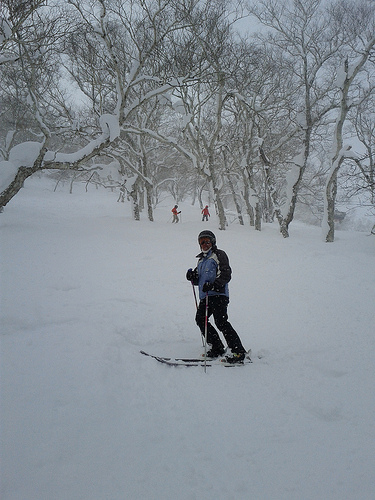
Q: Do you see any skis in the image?
A: Yes, there are skis.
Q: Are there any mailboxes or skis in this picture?
A: Yes, there are skis.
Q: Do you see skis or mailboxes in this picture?
A: Yes, there are skis.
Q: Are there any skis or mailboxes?
A: Yes, there are skis.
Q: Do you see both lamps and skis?
A: No, there are skis but no lamps.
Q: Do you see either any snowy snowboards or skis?
A: Yes, there are snowy skis.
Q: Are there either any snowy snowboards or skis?
A: Yes, there are snowy skis.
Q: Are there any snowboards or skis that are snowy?
A: Yes, the skis are snowy.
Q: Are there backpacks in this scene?
A: No, there are no backpacks.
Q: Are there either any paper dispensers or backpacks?
A: No, there are no backpacks or paper dispensers.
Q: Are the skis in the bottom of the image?
A: Yes, the skis are in the bottom of the image.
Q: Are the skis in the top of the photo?
A: No, the skis are in the bottom of the image.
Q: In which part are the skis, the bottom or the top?
A: The skis are in the bottom of the image.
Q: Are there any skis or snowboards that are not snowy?
A: No, there are skis but they are snowy.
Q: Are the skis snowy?
A: Yes, the skis are snowy.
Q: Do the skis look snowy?
A: Yes, the skis are snowy.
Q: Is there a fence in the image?
A: No, there are no fences.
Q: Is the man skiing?
A: Yes, the man is skiing.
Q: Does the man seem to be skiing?
A: Yes, the man is skiing.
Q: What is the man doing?
A: The man is skiing.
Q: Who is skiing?
A: The man is skiing.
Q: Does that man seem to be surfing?
A: No, the man is skiing.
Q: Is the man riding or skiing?
A: The man is skiing.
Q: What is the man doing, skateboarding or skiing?
A: The man is skiing.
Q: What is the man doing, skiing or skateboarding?
A: The man is skiing.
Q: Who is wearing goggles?
A: The man is wearing goggles.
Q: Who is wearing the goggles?
A: The man is wearing goggles.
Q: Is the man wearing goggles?
A: Yes, the man is wearing goggles.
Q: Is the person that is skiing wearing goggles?
A: Yes, the man is wearing goggles.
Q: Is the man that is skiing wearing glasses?
A: No, the man is wearing goggles.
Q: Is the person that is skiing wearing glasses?
A: No, the man is wearing goggles.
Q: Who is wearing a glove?
A: The man is wearing a glove.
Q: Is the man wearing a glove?
A: Yes, the man is wearing a glove.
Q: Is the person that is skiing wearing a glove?
A: Yes, the man is wearing a glove.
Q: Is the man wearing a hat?
A: No, the man is wearing a glove.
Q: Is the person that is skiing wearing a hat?
A: No, the man is wearing a glove.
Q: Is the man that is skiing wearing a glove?
A: Yes, the man is wearing a glove.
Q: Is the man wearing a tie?
A: No, the man is wearing a glove.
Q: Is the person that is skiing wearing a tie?
A: No, the man is wearing a glove.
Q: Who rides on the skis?
A: The man rides on the skis.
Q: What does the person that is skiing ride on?
A: The man rides on the skis.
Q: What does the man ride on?
A: The man rides on the skis.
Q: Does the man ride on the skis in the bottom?
A: Yes, the man rides on the skis.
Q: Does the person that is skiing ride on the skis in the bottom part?
A: Yes, the man rides on the skis.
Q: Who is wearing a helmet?
A: The man is wearing a helmet.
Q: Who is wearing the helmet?
A: The man is wearing a helmet.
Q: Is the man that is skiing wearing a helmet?
A: Yes, the man is wearing a helmet.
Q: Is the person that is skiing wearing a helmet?
A: Yes, the man is wearing a helmet.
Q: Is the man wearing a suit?
A: No, the man is wearing a helmet.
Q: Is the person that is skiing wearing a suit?
A: No, the man is wearing a helmet.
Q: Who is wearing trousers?
A: The man is wearing trousers.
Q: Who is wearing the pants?
A: The man is wearing trousers.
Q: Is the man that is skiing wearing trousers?
A: Yes, the man is wearing trousers.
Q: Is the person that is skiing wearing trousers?
A: Yes, the man is wearing trousers.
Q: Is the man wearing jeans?
A: No, the man is wearing trousers.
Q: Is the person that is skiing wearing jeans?
A: No, the man is wearing trousers.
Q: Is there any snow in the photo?
A: Yes, there is snow.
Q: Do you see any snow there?
A: Yes, there is snow.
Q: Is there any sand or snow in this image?
A: Yes, there is snow.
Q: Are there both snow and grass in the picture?
A: No, there is snow but no grass.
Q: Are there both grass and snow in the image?
A: No, there is snow but no grass.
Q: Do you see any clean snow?
A: Yes, there is clean snow.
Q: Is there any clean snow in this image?
A: Yes, there is clean snow.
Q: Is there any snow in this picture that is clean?
A: Yes, there is snow that is clean.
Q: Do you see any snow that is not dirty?
A: Yes, there is clean snow.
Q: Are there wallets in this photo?
A: No, there are no wallets.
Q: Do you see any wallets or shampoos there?
A: No, there are no wallets or shampoos.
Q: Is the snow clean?
A: Yes, the snow is clean.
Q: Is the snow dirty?
A: No, the snow is clean.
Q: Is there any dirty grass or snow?
A: No, there is snow but it is clean.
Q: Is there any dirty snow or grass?
A: No, there is snow but it is clean.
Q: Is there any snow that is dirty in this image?
A: No, there is snow but it is clean.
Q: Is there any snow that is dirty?
A: No, there is snow but it is clean.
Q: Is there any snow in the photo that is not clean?
A: No, there is snow but it is clean.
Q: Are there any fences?
A: No, there are no fences.